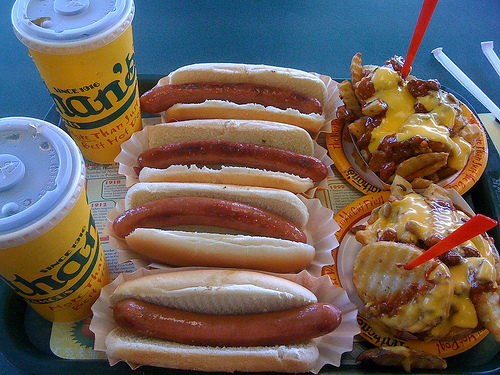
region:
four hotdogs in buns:
[142, 58, 327, 358]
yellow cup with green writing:
[7, 111, 118, 329]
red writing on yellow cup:
[20, 168, 120, 323]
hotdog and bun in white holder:
[97, 273, 377, 373]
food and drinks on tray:
[9, 57, 379, 182]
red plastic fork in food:
[337, 191, 499, 284]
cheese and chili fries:
[343, 61, 466, 191]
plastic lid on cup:
[4, 109, 104, 249]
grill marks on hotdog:
[138, 127, 320, 187]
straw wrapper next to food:
[423, 34, 498, 109]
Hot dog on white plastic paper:
[130, 61, 330, 123]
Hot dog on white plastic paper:
[112, 120, 342, 199]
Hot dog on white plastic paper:
[105, 177, 340, 274]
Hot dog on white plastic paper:
[85, 267, 358, 369]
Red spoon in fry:
[403, 210, 492, 286]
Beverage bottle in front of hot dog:
[1, 107, 121, 321]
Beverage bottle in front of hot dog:
[11, 0, 148, 159]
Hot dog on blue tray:
[136, 62, 340, 135]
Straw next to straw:
[430, 42, 498, 122]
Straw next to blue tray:
[427, 45, 498, 132]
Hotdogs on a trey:
[147, 47, 319, 374]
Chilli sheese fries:
[340, 55, 470, 180]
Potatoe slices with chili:
[353, 180, 489, 327]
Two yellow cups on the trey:
[0, 0, 128, 328]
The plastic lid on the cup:
[0, 112, 77, 247]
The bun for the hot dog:
[115, 334, 343, 374]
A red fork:
[395, 189, 498, 294]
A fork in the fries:
[395, 0, 437, 83]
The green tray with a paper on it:
[3, 322, 135, 374]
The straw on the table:
[432, 25, 498, 95]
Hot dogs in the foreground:
[103, 56, 355, 374]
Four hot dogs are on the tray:
[113, 43, 346, 367]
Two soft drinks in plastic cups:
[3, 1, 145, 333]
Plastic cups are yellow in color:
[2, 0, 144, 337]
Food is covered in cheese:
[333, 51, 493, 329]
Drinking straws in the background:
[422, 34, 497, 119]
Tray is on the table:
[3, 18, 496, 370]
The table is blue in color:
[1, 3, 496, 133]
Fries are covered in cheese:
[337, 45, 449, 180]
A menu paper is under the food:
[44, 105, 454, 365]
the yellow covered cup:
[9, 6, 153, 163]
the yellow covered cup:
[0, 113, 110, 337]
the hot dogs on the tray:
[115, 64, 345, 359]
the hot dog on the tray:
[93, 267, 352, 373]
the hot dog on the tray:
[103, 180, 339, 277]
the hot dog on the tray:
[115, 115, 330, 182]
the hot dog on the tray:
[136, 58, 331, 125]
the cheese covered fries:
[335, 178, 497, 338]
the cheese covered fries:
[335, 71, 483, 198]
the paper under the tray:
[85, 163, 127, 215]